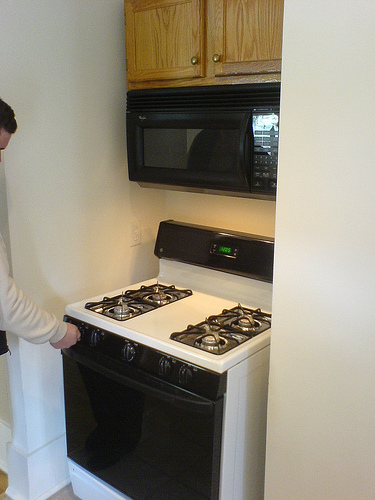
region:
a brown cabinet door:
[119, 0, 210, 80]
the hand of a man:
[51, 325, 82, 354]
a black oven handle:
[52, 345, 212, 413]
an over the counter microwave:
[123, 82, 282, 202]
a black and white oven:
[54, 217, 275, 498]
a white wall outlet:
[127, 217, 145, 249]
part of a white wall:
[0, 1, 169, 319]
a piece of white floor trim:
[6, 445, 66, 497]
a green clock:
[218, 243, 233, 252]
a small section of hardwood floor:
[0, 470, 6, 490]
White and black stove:
[60, 217, 271, 496]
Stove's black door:
[56, 315, 224, 496]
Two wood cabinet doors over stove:
[121, 0, 275, 91]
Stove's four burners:
[83, 277, 271, 358]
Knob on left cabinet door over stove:
[203, 46, 224, 62]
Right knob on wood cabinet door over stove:
[177, 46, 202, 71]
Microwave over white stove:
[118, 81, 300, 204]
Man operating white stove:
[0, 96, 80, 496]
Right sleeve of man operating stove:
[0, 271, 71, 356]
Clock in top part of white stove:
[208, 232, 244, 270]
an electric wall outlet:
[128, 218, 145, 248]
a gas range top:
[67, 274, 272, 372]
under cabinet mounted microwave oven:
[121, 89, 285, 202]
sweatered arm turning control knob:
[0, 265, 83, 353]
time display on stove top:
[206, 235, 244, 262]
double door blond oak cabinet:
[121, 2, 280, 89]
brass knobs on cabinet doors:
[188, 53, 221, 66]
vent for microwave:
[123, 85, 282, 108]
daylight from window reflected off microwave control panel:
[248, 106, 281, 195]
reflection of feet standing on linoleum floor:
[60, 353, 224, 498]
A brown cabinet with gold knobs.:
[122, 0, 280, 82]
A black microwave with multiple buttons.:
[124, 90, 270, 183]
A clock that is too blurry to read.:
[211, 241, 234, 252]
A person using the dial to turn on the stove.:
[2, 277, 80, 352]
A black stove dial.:
[120, 340, 135, 355]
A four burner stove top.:
[75, 270, 262, 350]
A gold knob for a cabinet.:
[188, 53, 194, 62]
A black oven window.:
[61, 380, 217, 488]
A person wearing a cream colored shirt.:
[0, 270, 78, 356]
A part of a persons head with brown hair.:
[0, 96, 17, 150]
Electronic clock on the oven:
[217, 245, 233, 255]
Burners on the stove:
[85, 272, 270, 356]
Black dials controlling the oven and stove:
[65, 313, 202, 386]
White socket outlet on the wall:
[127, 221, 144, 247]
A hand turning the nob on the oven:
[49, 318, 80, 353]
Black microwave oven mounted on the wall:
[124, 89, 277, 200]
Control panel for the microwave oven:
[250, 112, 276, 196]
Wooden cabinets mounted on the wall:
[124, 1, 281, 87]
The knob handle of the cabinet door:
[188, 53, 199, 64]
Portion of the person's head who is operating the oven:
[0, 97, 17, 160]